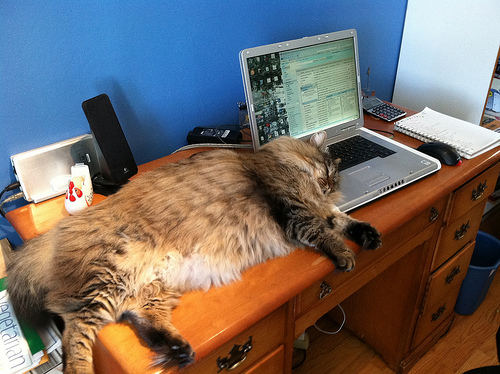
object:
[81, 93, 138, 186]
speaker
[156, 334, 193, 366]
foot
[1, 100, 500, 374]
desk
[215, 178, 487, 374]
brass fittings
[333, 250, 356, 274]
paw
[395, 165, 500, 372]
drawers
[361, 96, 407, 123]
calculator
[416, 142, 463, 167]
mouse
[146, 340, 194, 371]
toes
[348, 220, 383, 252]
toes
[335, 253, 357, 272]
toes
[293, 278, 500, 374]
floor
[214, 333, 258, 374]
handle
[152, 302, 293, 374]
drawer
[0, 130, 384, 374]
cat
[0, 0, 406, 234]
wall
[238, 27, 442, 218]
computer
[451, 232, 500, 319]
waste basket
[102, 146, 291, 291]
fur